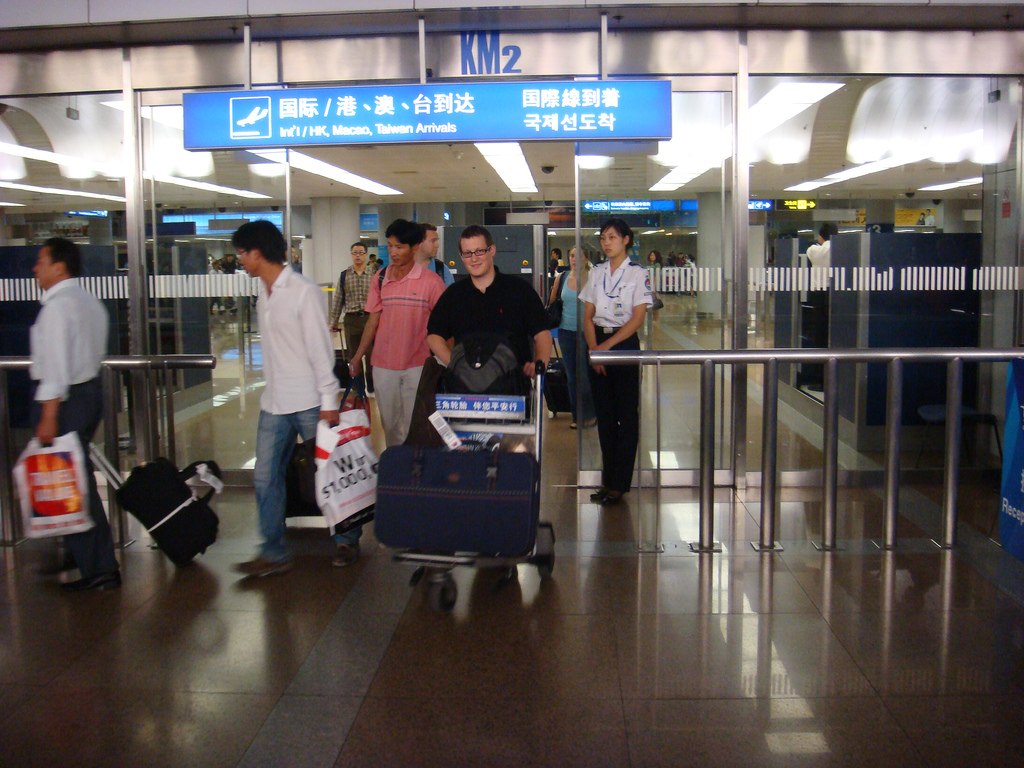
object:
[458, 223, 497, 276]
head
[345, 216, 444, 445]
person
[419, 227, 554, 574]
person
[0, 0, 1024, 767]
airport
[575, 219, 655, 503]
person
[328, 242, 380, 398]
person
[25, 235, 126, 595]
person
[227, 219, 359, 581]
person